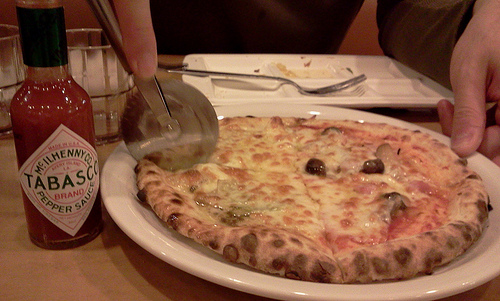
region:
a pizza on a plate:
[130, 113, 492, 285]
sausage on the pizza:
[297, 150, 383, 180]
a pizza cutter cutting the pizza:
[86, 0, 220, 177]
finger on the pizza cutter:
[89, 1, 164, 87]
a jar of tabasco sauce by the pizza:
[2, 1, 104, 258]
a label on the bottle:
[21, 124, 96, 236]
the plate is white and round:
[86, 94, 498, 296]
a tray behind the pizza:
[177, 49, 460, 112]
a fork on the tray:
[156, 59, 370, 103]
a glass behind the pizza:
[56, 27, 139, 144]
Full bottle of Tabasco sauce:
[10, 0, 104, 247]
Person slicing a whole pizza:
[98, 0, 495, 295]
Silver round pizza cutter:
[87, 0, 220, 168]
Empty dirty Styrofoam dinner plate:
[179, 50, 455, 108]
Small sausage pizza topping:
[302, 154, 326, 178]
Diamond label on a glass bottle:
[16, 120, 98, 235]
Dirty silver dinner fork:
[166, 65, 366, 93]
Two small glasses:
[0, 20, 133, 146]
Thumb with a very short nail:
[447, 38, 488, 154]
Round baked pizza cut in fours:
[135, 113, 490, 284]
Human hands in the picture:
[111, 4, 497, 154]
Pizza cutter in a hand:
[89, 2, 218, 168]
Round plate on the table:
[103, 104, 498, 299]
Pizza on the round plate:
[137, 117, 494, 284]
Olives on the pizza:
[306, 156, 384, 176]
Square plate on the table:
[180, 52, 454, 111]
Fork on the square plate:
[163, 60, 368, 97]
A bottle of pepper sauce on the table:
[10, 3, 100, 248]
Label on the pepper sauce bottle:
[13, 123, 99, 236]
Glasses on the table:
[0, 25, 131, 145]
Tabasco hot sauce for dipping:
[6, 3, 116, 246]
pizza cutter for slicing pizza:
[92, 3, 218, 170]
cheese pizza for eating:
[128, 110, 490, 277]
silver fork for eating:
[161, 60, 373, 95]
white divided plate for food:
[186, 48, 458, 109]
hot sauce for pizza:
[8, 1, 116, 242]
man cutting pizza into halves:
[96, 2, 496, 282]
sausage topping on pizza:
[303, 155, 330, 178]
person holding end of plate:
[419, 5, 499, 154]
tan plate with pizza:
[92, 99, 498, 297]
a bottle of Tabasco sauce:
[11, 2, 111, 256]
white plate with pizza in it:
[85, 71, 499, 297]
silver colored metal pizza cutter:
[114, 0, 226, 171]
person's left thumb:
[433, 0, 498, 165]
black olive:
[304, 145, 329, 182]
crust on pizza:
[186, 205, 340, 292]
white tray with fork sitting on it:
[182, 47, 468, 112]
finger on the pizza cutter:
[99, 3, 233, 180]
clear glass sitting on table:
[23, 28, 155, 299]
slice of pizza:
[296, 153, 499, 285]